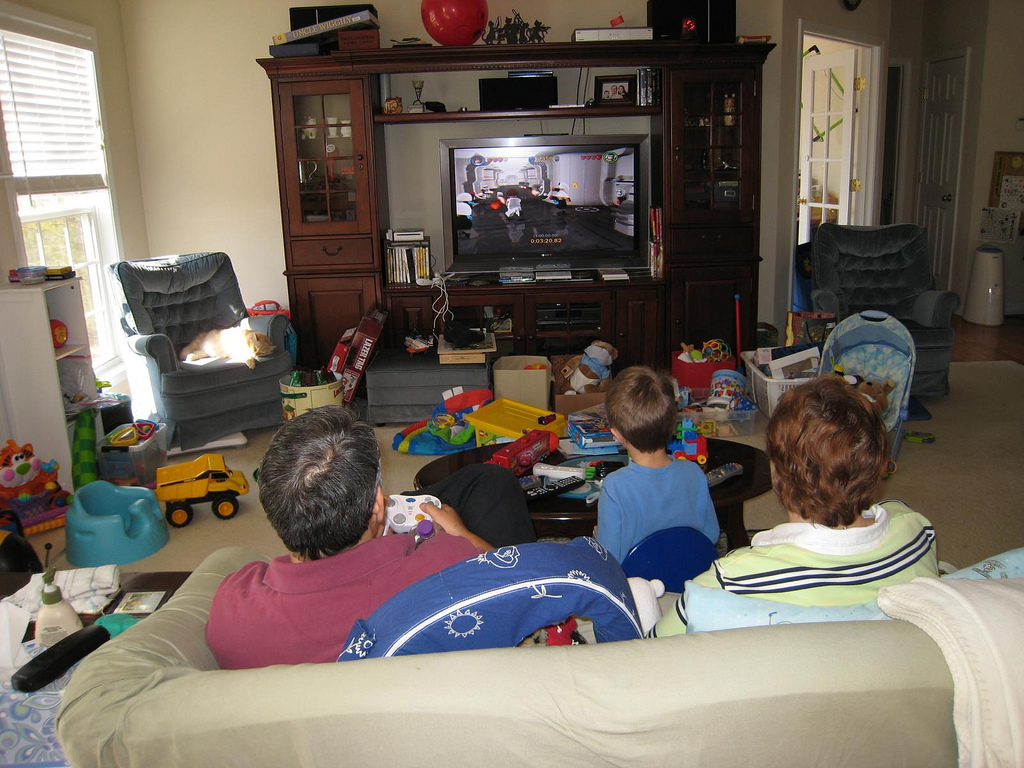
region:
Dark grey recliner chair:
[111, 246, 307, 447]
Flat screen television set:
[438, 129, 661, 284]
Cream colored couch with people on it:
[52, 540, 1018, 766]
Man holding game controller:
[198, 404, 497, 671]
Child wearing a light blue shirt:
[582, 363, 731, 561]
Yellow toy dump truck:
[147, 445, 252, 529]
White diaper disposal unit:
[958, 240, 1009, 327]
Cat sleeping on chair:
[175, 319, 277, 374]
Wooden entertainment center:
[257, 33, 767, 376]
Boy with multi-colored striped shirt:
[650, 382, 951, 630]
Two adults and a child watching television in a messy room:
[3, 53, 939, 668]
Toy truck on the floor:
[155, 456, 247, 534]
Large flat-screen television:
[442, 127, 649, 282]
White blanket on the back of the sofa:
[875, 555, 1021, 762]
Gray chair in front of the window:
[111, 239, 299, 449]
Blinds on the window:
[3, 21, 111, 199]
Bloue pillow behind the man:
[335, 535, 639, 660]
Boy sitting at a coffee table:
[410, 361, 778, 549]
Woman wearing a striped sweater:
[680, 360, 940, 637]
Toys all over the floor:
[66, 306, 949, 632]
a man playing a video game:
[205, 412, 528, 670]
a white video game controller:
[376, 495, 438, 538]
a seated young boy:
[597, 369, 721, 588]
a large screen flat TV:
[442, 137, 652, 271]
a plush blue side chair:
[110, 251, 294, 449]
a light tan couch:
[59, 535, 1023, 767]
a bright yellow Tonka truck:
[157, 454, 249, 528]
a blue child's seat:
[60, 481, 169, 565]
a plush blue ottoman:
[367, 336, 486, 428]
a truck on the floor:
[159, 421, 245, 502]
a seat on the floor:
[82, 486, 203, 572]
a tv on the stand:
[451, 128, 652, 288]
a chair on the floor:
[94, 235, 263, 406]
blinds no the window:
[25, 26, 105, 172]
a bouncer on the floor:
[824, 306, 919, 477]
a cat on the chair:
[200, 292, 251, 362]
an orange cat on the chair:
[133, 292, 216, 369]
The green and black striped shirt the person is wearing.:
[676, 496, 952, 621]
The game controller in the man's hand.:
[382, 490, 441, 529]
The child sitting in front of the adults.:
[600, 363, 722, 582]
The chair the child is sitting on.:
[633, 530, 716, 592]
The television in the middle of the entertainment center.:
[442, 144, 657, 275]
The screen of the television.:
[447, 144, 635, 259]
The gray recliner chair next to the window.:
[106, 249, 285, 447]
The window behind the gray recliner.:
[5, 25, 136, 386]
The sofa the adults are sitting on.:
[74, 553, 1021, 763]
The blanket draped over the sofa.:
[872, 574, 1022, 759]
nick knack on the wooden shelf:
[413, 0, 503, 58]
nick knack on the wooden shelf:
[529, 15, 553, 45]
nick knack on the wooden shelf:
[509, 9, 529, 42]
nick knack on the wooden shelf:
[482, 17, 498, 43]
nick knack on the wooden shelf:
[399, 68, 429, 106]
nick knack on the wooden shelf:
[381, 92, 405, 106]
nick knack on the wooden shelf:
[588, 63, 640, 109]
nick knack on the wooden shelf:
[471, 69, 555, 118]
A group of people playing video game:
[221, 347, 893, 695]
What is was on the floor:
[399, 326, 597, 557]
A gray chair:
[746, 185, 975, 455]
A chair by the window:
[0, 136, 294, 487]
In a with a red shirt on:
[130, 352, 507, 679]